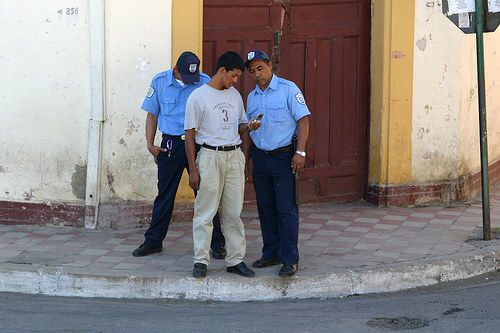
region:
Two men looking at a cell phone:
[185, 52, 309, 273]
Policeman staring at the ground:
[133, 52, 211, 260]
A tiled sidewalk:
[1, 205, 498, 279]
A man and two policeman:
[143, 50, 310, 275]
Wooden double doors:
[171, 1, 412, 209]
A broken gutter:
[82, 1, 107, 232]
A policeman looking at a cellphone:
[241, 50, 311, 279]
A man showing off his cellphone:
[190, 52, 263, 277]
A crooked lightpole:
[467, 1, 497, 242]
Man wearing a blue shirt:
[233, 43, 318, 278]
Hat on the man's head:
[241, 47, 272, 67]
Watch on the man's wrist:
[289, 142, 311, 160]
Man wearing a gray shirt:
[183, 49, 263, 279]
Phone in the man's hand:
[245, 111, 265, 131]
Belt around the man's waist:
[196, 135, 245, 156]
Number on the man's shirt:
[213, 100, 233, 126]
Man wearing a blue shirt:
[131, 45, 234, 258]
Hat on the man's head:
[170, 46, 207, 85]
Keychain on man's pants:
[163, 135, 177, 160]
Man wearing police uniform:
[246, 46, 311, 276]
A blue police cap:
[176, 50, 201, 83]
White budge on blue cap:
[186, 63, 198, 74]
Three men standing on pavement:
[131, 45, 313, 282]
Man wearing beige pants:
[191, 147, 248, 268]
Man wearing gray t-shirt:
[185, 52, 247, 149]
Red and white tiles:
[297, 204, 481, 261]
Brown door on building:
[205, 3, 368, 203]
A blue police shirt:
[246, 76, 307, 149]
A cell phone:
[258, 114, 263, 119]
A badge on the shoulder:
[148, 90, 152, 95]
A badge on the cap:
[190, 66, 195, 72]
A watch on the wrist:
[301, 153, 304, 155]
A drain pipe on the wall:
[91, 44, 101, 116]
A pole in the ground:
[478, 49, 485, 154]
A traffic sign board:
[445, 3, 497, 13]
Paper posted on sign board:
[450, 2, 470, 10]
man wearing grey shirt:
[183, 48, 263, 280]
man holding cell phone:
[249, 109, 265, 128]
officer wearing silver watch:
[296, 148, 307, 158]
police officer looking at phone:
[236, 47, 313, 284]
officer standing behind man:
[133, 48, 228, 264]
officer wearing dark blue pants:
[250, 145, 300, 267]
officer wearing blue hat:
[176, 48, 200, 80]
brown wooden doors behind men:
[201, 0, 369, 210]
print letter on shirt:
[213, 102, 219, 108]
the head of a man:
[237, 38, 279, 87]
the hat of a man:
[242, 40, 271, 67]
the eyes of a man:
[244, 66, 265, 73]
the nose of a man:
[250, 64, 263, 83]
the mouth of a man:
[255, 74, 265, 80]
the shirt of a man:
[233, 74, 311, 153]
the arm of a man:
[273, 81, 322, 178]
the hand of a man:
[282, 149, 311, 172]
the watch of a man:
[291, 141, 314, 162]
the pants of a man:
[246, 145, 303, 261]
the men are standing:
[122, 53, 314, 270]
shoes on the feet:
[177, 258, 239, 278]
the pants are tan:
[224, 226, 246, 236]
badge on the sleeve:
[292, 90, 309, 106]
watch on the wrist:
[288, 145, 308, 153]